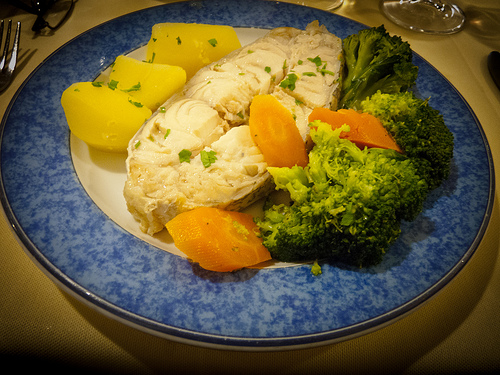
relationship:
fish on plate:
[123, 18, 346, 236] [440, 71, 498, 272]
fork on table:
[3, 14, 24, 90] [6, 5, 498, 365]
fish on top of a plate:
[123, 18, 346, 236] [18, 18, 475, 333]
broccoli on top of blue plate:
[257, 22, 454, 273] [0, 0, 493, 352]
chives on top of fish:
[199, 149, 219, 168] [123, 16, 346, 238]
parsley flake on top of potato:
[206, 32, 224, 52] [135, 15, 246, 77]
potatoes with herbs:
[92, 46, 182, 94] [92, 69, 143, 108]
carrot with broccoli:
[241, 92, 316, 189] [223, 58, 400, 160]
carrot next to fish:
[140, 167, 285, 309] [125, 95, 266, 212]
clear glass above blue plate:
[377, 3, 466, 34] [0, 0, 493, 352]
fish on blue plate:
[123, 18, 346, 236] [0, 0, 493, 352]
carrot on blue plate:
[241, 92, 316, 189] [0, 0, 493, 352]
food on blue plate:
[91, 32, 444, 264] [0, 0, 493, 352]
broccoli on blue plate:
[257, 22, 454, 273] [0, 0, 493, 352]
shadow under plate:
[89, 315, 151, 368] [37, 234, 316, 346]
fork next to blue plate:
[0, 14, 22, 95] [0, 0, 493, 352]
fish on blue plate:
[123, 16, 346, 238] [0, 0, 497, 352]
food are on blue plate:
[58, 18, 454, 275] [0, 0, 497, 352]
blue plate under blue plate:
[0, 0, 493, 352] [0, 0, 493, 352]